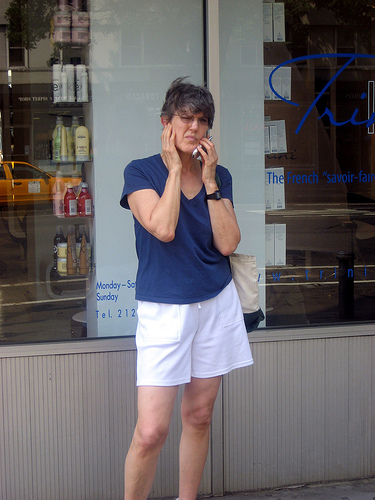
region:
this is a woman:
[77, 49, 263, 499]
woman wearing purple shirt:
[120, 133, 246, 319]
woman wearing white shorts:
[103, 272, 254, 387]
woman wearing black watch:
[209, 186, 228, 201]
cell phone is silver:
[179, 136, 222, 166]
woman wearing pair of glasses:
[162, 101, 219, 128]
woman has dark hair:
[154, 85, 223, 125]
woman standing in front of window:
[17, 27, 373, 392]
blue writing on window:
[79, 260, 143, 331]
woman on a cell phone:
[123, 75, 242, 285]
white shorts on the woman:
[123, 277, 259, 387]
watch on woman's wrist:
[201, 180, 227, 205]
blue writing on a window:
[267, 34, 374, 195]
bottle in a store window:
[73, 123, 91, 163]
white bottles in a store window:
[75, 60, 91, 113]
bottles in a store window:
[62, 176, 96, 217]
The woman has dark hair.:
[159, 70, 228, 125]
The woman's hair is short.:
[150, 68, 220, 131]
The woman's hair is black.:
[145, 69, 222, 122]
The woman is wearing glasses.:
[156, 105, 218, 127]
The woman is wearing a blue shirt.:
[120, 146, 250, 302]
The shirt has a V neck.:
[151, 155, 212, 206]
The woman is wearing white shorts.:
[122, 287, 262, 383]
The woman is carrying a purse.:
[217, 238, 271, 334]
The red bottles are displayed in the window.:
[59, 175, 104, 229]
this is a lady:
[106, 83, 256, 496]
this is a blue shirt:
[120, 151, 251, 299]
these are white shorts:
[121, 283, 248, 392]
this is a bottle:
[71, 117, 95, 159]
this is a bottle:
[52, 117, 69, 166]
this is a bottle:
[58, 110, 85, 169]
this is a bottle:
[78, 181, 95, 221]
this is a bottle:
[60, 178, 79, 218]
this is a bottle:
[54, 165, 69, 225]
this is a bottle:
[48, 220, 80, 282]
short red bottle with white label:
[64, 183, 75, 216]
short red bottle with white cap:
[77, 182, 90, 216]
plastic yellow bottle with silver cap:
[73, 124, 86, 159]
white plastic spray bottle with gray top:
[61, 65, 68, 99]